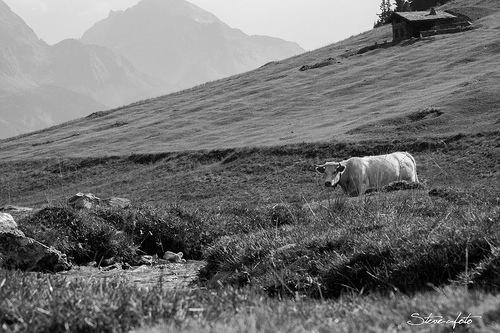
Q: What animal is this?
A: Cow.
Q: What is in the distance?
A: Mountain.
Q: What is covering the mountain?
A: Fog.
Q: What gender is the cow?
A: Female.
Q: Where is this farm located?
A: Mountains.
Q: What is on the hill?
A: House.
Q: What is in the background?
A: Mountains.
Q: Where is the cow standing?
A: Pasture.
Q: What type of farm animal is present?
A: Cow.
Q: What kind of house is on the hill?
A: Log cabin.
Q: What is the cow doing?
A: Grazing.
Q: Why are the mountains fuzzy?
A: Fog.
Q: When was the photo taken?
A: Daytime.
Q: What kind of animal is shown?
A: Cow.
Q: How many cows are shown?
A: One.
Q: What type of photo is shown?
A: Black and white.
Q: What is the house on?
A: Hill.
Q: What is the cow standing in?
A: Grass.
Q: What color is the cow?
A: White.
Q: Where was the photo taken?
A: In a field.